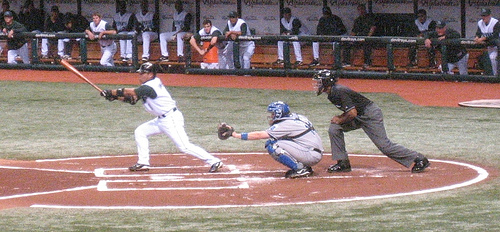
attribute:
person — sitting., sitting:
[407, 9, 435, 65]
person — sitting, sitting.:
[343, 4, 386, 70]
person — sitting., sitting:
[311, 2, 346, 64]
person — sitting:
[274, 6, 302, 69]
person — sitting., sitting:
[159, 0, 192, 58]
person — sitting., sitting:
[130, 0, 159, 62]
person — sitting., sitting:
[36, 5, 67, 53]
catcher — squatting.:
[258, 101, 322, 176]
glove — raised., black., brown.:
[212, 123, 238, 141]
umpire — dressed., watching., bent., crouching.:
[317, 76, 431, 175]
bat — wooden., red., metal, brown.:
[53, 60, 116, 98]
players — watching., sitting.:
[3, 9, 496, 75]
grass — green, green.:
[1, 81, 497, 226]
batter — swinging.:
[113, 66, 223, 170]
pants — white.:
[132, 109, 215, 174]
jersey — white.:
[142, 78, 177, 119]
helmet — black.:
[137, 60, 156, 76]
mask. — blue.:
[266, 102, 293, 124]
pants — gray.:
[330, 106, 416, 168]